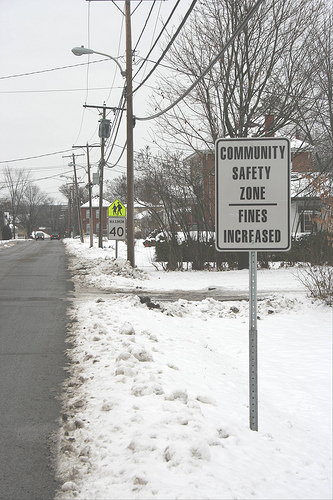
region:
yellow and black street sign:
[109, 189, 127, 215]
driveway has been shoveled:
[98, 276, 234, 308]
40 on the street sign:
[102, 215, 128, 240]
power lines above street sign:
[88, 100, 143, 166]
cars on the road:
[28, 226, 65, 245]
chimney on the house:
[237, 105, 299, 142]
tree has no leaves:
[186, 3, 330, 102]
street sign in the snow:
[163, 336, 330, 491]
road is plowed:
[36, 322, 85, 421]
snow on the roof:
[86, 182, 114, 209]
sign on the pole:
[205, 135, 286, 252]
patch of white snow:
[210, 470, 225, 486]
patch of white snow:
[265, 477, 286, 494]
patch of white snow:
[287, 414, 311, 440]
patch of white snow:
[173, 473, 196, 493]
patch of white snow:
[286, 398, 301, 419]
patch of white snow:
[298, 365, 319, 387]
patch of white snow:
[172, 438, 191, 457]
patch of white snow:
[197, 351, 223, 367]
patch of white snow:
[115, 453, 129, 473]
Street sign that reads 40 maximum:
[106, 215, 126, 240]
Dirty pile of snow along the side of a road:
[66, 254, 151, 282]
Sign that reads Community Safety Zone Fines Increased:
[215, 136, 292, 252]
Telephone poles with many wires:
[0, 0, 330, 266]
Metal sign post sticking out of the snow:
[247, 251, 259, 430]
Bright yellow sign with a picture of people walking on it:
[107, 199, 126, 217]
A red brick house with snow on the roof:
[79, 194, 112, 234]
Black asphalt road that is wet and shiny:
[2, 235, 75, 498]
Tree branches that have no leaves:
[0, 0, 330, 271]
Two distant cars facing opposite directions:
[33, 230, 60, 241]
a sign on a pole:
[238, 114, 295, 276]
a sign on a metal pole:
[194, 139, 282, 304]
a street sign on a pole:
[156, 115, 331, 354]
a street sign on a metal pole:
[192, 137, 331, 355]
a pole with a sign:
[194, 136, 301, 326]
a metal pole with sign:
[214, 126, 330, 297]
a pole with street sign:
[197, 141, 289, 283]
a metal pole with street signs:
[190, 105, 315, 345]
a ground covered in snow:
[119, 324, 281, 495]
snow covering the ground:
[117, 319, 259, 485]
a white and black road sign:
[212, 135, 294, 252]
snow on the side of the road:
[71, 292, 199, 496]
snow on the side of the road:
[66, 238, 116, 297]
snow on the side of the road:
[0, 236, 28, 254]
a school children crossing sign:
[103, 195, 131, 216]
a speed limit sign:
[105, 218, 126, 267]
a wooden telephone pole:
[119, 2, 143, 269]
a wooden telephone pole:
[95, 99, 105, 252]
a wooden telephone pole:
[82, 139, 94, 248]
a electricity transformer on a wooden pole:
[97, 114, 112, 142]